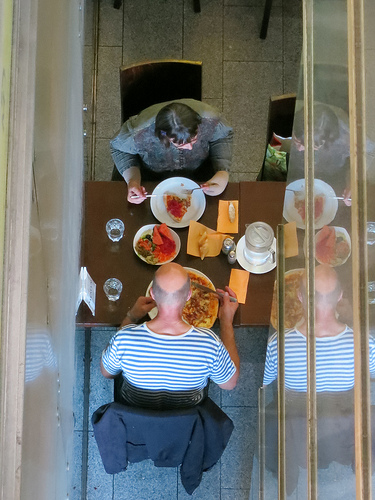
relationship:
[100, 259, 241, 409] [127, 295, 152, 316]
man has hand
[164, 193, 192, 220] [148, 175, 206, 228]
food on plate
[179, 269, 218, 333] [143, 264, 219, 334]
food on white plate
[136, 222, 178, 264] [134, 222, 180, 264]
food on plate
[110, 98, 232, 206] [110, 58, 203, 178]
woman sitting on chair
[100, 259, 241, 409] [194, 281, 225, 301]
man holding knife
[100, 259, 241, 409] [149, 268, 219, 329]
man cutting food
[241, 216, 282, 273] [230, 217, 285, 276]
pitcher on a plate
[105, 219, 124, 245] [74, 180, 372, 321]
glass sitting on a table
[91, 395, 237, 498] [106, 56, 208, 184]
jacket on chair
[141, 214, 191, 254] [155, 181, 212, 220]
food on plate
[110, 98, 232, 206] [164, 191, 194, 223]
woman with food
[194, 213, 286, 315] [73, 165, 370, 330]
napkins on table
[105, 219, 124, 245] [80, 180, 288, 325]
glass on table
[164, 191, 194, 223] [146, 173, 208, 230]
food served on plate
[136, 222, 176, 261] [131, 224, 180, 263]
food sitting on white plate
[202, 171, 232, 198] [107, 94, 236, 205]
hand of person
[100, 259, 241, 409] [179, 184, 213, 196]
man holding fork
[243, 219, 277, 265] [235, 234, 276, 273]
pitcher on plate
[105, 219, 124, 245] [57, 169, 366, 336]
glass on table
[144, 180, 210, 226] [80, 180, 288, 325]
plate on table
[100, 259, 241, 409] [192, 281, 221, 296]
man holding knife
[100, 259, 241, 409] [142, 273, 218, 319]
man eating food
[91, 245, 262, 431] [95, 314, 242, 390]
man in shirt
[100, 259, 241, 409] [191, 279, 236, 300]
man holding knife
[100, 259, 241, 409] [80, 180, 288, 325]
man sitting at a table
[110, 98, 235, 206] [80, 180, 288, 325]
woman sitting at a table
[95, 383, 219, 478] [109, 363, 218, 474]
jacket draped behind a chair